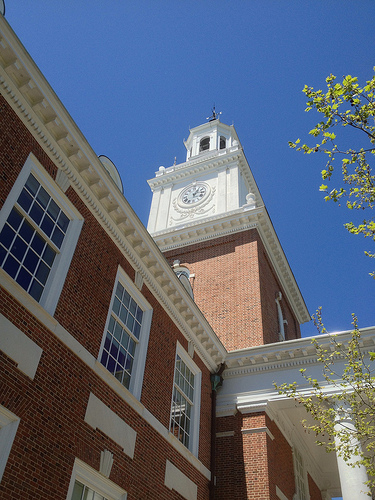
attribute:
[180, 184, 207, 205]
clock — round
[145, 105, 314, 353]
tower — bell tower, white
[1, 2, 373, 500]
building — large, red brick, brick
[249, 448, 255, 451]
brick — red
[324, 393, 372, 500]
column — architectural, white, large, pillar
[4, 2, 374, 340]
sky — cloudless, clear, blue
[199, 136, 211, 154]
opening — for bell tower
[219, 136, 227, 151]
opening — for bell tower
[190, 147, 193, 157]
opening — for bell tower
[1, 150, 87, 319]
window — at left, glass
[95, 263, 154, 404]
window — at middle, glass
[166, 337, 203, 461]
window — at right, 1st window, glass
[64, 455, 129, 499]
window — at middle, glass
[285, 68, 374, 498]
tree — budding, large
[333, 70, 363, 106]
leaves — green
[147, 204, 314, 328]
trim — white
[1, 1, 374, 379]
trim — white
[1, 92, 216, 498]
wall — brown, brick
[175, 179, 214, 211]
background — white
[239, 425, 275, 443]
decoration — white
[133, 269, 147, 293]
decoration — white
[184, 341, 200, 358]
decoration — white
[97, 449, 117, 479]
decoration — white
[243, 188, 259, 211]
decoration — white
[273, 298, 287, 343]
window — arched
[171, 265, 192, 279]
window — arched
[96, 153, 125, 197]
window — arched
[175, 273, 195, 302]
window — arched